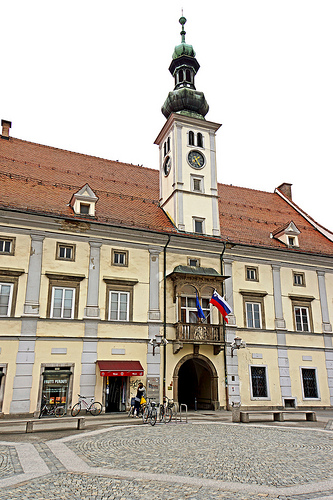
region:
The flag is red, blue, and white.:
[206, 284, 235, 320]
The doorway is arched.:
[172, 347, 222, 415]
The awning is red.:
[97, 360, 147, 379]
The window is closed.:
[247, 302, 264, 329]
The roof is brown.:
[2, 133, 325, 249]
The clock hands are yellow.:
[187, 147, 206, 169]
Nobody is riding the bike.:
[71, 394, 102, 418]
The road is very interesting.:
[7, 421, 331, 495]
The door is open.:
[105, 378, 124, 407]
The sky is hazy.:
[7, 5, 330, 227]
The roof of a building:
[0, 130, 329, 254]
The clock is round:
[180, 146, 204, 168]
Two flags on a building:
[185, 284, 233, 323]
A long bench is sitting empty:
[0, 409, 85, 435]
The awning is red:
[89, 350, 140, 375]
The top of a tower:
[154, 2, 210, 115]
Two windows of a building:
[40, 270, 135, 322]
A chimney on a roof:
[0, 113, 13, 137]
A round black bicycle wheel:
[85, 396, 100, 416]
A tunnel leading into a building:
[167, 350, 225, 411]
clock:
[180, 147, 208, 167]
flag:
[195, 284, 250, 325]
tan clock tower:
[166, 24, 220, 188]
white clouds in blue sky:
[235, 49, 276, 89]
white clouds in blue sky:
[288, 116, 319, 149]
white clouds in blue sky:
[261, 45, 292, 70]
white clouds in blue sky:
[69, 46, 111, 85]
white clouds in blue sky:
[29, 38, 75, 83]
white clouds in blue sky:
[93, 9, 131, 49]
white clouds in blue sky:
[45, 68, 73, 96]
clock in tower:
[173, 143, 205, 172]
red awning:
[97, 343, 153, 387]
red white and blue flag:
[198, 286, 234, 319]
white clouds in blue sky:
[230, 18, 306, 79]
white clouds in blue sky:
[233, 76, 277, 111]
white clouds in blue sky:
[259, 89, 286, 114]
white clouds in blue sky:
[30, 61, 59, 90]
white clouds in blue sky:
[84, 47, 102, 65]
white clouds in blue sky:
[252, 76, 273, 90]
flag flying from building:
[210, 288, 228, 317]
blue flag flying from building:
[193, 298, 204, 319]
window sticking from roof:
[70, 183, 100, 217]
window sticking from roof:
[273, 219, 302, 249]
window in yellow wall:
[47, 283, 76, 319]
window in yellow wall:
[107, 286, 130, 323]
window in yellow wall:
[243, 299, 264, 328]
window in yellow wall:
[294, 303, 311, 330]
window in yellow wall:
[303, 368, 317, 398]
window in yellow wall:
[250, 365, 268, 399]